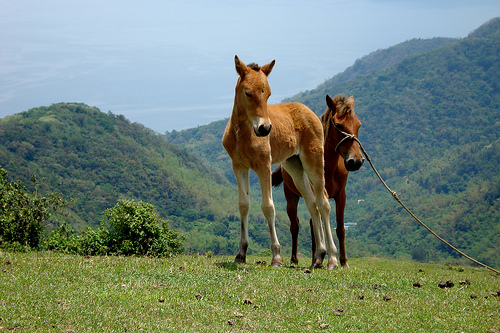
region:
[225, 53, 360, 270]
Two horses in the grass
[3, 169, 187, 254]
Small bushes on the ground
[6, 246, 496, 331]
Green grass on the field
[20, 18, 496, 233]
Distant, mountainous range in the background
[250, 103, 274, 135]
Snout of a horse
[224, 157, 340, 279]
Legs on a horse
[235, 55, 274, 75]
Ears on top of a horse's head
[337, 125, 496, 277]
Rope connected to a horse's snout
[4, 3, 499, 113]
A blue sky with thin, wispy clouds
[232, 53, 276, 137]
Head of a young horse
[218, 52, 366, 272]
two brown horses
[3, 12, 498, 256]
the green hills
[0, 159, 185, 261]
bushes on the left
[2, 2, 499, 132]
the fair sky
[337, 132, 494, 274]
the rope on horse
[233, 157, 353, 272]
the long legs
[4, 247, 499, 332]
the green grass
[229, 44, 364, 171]
the heads of horses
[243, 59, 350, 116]
mane of horses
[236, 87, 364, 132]
the slanted eyes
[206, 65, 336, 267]
a brown and white colt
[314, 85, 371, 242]
a brown horse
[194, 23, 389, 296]
two horses standing on hilltop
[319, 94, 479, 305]
a horse with a rope tied to it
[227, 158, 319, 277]
a colt with white legs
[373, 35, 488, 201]
a hill side covered with trees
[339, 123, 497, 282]
a long rope tied to a horses head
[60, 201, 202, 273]
a small green bush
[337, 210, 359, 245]
a building in a valley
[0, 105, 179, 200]
a mountain side covered with trees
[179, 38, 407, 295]
two ponies on a hill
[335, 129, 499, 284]
a rope on one pony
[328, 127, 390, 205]
rope tied around mouth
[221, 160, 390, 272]
white legs of a pony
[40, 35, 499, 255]
mountains in the background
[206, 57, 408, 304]
two ponies standing in grass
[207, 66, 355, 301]
a light brown pony with white legs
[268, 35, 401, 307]
a dark brown pony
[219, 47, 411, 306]
one pony behind the other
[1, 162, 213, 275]
some shrubs to the left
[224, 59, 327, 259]
BROWN BABY HORSE ON GRASS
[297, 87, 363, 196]
BROWN BABY HORSE ON GRASS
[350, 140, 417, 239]
ROPE TIED TO BABY HORSE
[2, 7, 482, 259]
MOUNTAINS IN THE BACKGROUND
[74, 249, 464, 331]
GRASS GROWING UNDER HORSES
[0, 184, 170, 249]
SMALL BUSHES ON CLIFFSIDE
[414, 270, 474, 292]
DIRT TURNED UP IN GRASS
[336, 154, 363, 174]
BLACK NOSE OF HORSE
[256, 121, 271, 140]
BLACK NOSE OF HORSE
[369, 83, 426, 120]
THICK FOREST COVERING MOUNTAINS